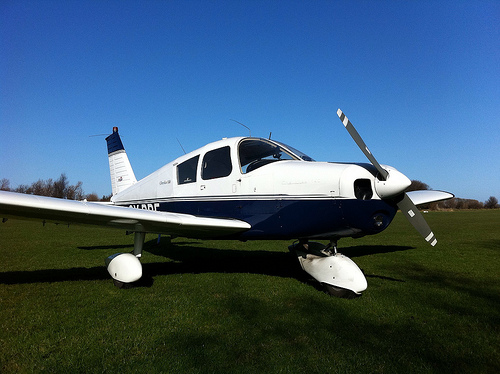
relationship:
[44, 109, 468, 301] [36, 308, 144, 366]
airplane on ground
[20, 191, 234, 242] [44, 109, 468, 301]
wing on airplane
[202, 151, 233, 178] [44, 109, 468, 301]
window on airplane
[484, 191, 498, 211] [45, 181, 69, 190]
tree has leaves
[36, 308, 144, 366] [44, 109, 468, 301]
ground under airplane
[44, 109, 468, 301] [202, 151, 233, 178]
airplane has a window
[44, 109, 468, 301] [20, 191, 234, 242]
airplane has a wing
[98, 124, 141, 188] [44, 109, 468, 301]
tail of airplane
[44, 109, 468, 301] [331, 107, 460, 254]
airplane has propeller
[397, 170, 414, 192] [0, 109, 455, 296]
nose of airplane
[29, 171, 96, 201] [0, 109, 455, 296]
trees behind airplane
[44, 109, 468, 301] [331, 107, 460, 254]
airplane has a propeller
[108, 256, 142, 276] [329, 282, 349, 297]
covers on wheels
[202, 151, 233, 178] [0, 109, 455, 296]
window on side of airplane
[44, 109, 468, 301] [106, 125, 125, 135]
airplane has a tail light